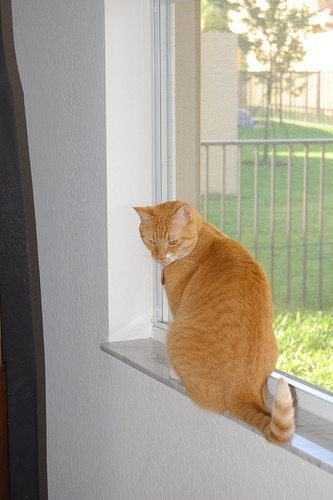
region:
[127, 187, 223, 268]
Orange cat looking grumpy.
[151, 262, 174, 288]
The cat is wearing a collar with a red tag.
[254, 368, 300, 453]
Orange and creme striped tail.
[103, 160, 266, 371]
Cat sitting on the window ledge.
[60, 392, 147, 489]
White walls in the house.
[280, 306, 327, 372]
Green grass filled with sunlight.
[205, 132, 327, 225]
Metal fence in the backyard.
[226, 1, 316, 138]
Skinny tree in the next yard.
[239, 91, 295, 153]
Stakes holding the small tree up.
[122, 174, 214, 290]
The cat is name Marmalade.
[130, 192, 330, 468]
A cat on a window sill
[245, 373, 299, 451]
The tail of a cat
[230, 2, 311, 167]
Small tree outside the window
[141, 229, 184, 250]
A pair of cat eyes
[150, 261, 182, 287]
Tag on a collar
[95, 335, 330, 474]
A gray marble window sill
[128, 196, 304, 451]
The cat is orange and white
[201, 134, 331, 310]
The bars of a fence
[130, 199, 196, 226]
Two pointy ears of a cat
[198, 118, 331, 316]
Shadows on the grass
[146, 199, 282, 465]
the cat is orange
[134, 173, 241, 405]
the cat is orange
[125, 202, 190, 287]
the cat is looking down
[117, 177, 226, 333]
the cat is looking down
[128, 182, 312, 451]
A cat in the foreground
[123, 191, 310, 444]
The cat is orange in color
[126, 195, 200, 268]
Cat is looking down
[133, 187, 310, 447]
Cat is sitting down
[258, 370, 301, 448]
Cat's tail is sticking up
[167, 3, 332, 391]
Cat is near a window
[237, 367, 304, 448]
Cat's tail is striped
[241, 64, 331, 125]
A fence in the background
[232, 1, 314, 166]
A small tree in the background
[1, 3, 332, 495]
Photo was taken indoors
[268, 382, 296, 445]
Tan and white cat tail.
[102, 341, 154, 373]
Grey corner of a window seal.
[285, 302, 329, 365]
Patch of green grass outside.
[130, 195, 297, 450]
Cat sitting in the window.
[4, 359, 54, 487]
Bottom piece of bedpost.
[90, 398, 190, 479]
Patch of a white wall.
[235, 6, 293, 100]
Small tree outside the window.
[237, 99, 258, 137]
Small black grill outside of yard.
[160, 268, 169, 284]
Red collar around cat's neck.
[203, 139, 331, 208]
Silver fence outside of residence.